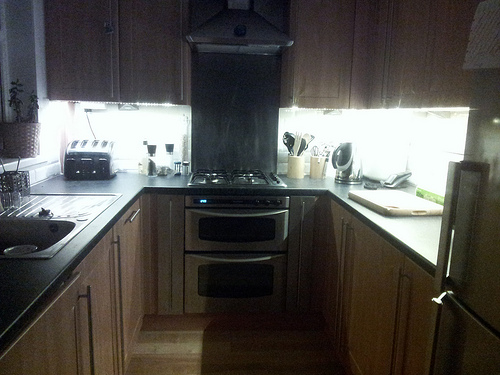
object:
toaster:
[62, 139, 117, 182]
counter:
[39, 149, 375, 193]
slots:
[101, 140, 109, 150]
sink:
[0, 217, 70, 256]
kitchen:
[0, 0, 500, 375]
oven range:
[180, 166, 293, 315]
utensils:
[311, 143, 331, 181]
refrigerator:
[421, 107, 500, 375]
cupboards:
[52, 8, 174, 106]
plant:
[4, 72, 40, 158]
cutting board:
[345, 188, 449, 217]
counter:
[322, 172, 458, 273]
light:
[293, 97, 474, 123]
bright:
[344, 106, 378, 119]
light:
[52, 97, 188, 118]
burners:
[197, 176, 226, 186]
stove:
[191, 169, 285, 188]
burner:
[234, 176, 267, 186]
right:
[231, 170, 267, 186]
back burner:
[230, 171, 262, 176]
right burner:
[232, 169, 266, 186]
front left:
[189, 174, 228, 186]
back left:
[192, 169, 226, 174]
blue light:
[232, 24, 248, 37]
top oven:
[184, 205, 293, 250]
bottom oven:
[172, 250, 291, 312]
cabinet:
[0, 190, 148, 375]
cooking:
[281, 129, 367, 186]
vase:
[286, 156, 305, 180]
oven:
[181, 206, 291, 254]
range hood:
[180, 6, 296, 57]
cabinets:
[42, 1, 497, 104]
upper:
[40, 3, 493, 92]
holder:
[310, 155, 329, 180]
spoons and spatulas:
[282, 132, 314, 156]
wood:
[382, 195, 420, 211]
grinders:
[143, 143, 159, 179]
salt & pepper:
[173, 159, 190, 176]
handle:
[436, 159, 459, 294]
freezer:
[449, 107, 500, 373]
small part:
[48, 177, 119, 195]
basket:
[5, 119, 40, 159]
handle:
[421, 291, 454, 375]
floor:
[129, 314, 340, 372]